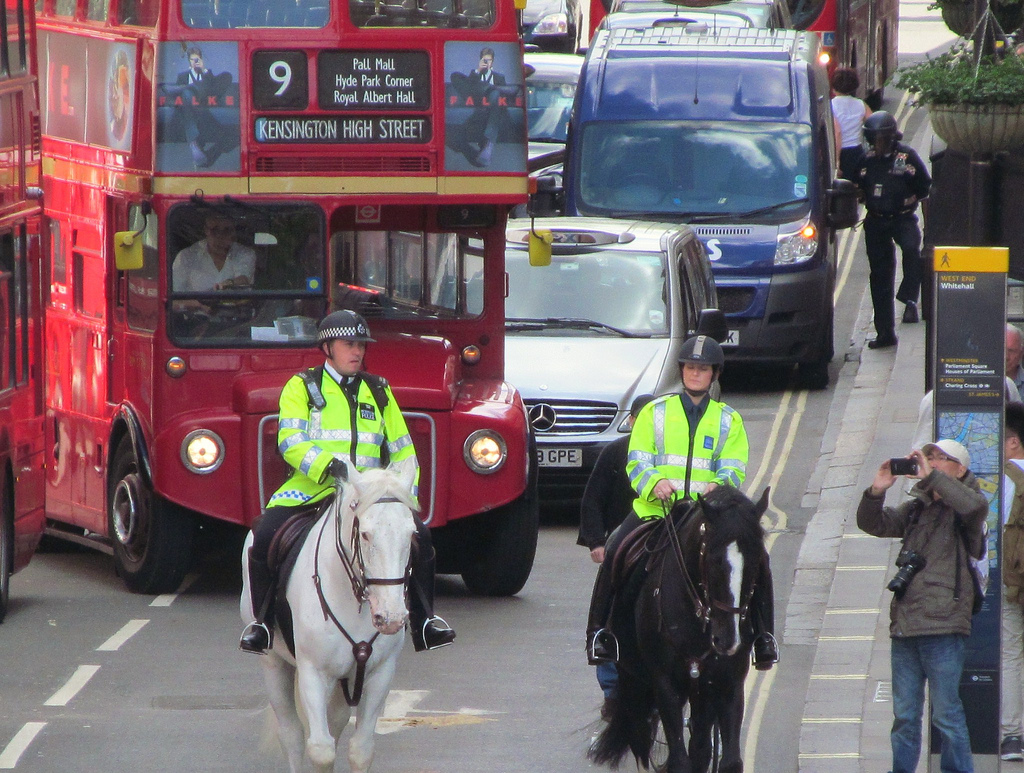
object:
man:
[238, 310, 457, 654]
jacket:
[266, 359, 422, 509]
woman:
[586, 334, 780, 671]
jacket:
[625, 392, 749, 520]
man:
[855, 439, 987, 773]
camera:
[890, 457, 918, 475]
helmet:
[318, 309, 378, 349]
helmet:
[677, 335, 724, 374]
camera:
[885, 557, 928, 600]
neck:
[931, 490, 944, 502]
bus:
[20, 2, 552, 597]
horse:
[584, 480, 779, 773]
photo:
[0, 0, 1024, 773]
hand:
[325, 458, 349, 484]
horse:
[239, 455, 453, 773]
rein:
[312, 492, 405, 706]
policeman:
[852, 109, 932, 348]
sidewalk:
[778, 327, 912, 772]